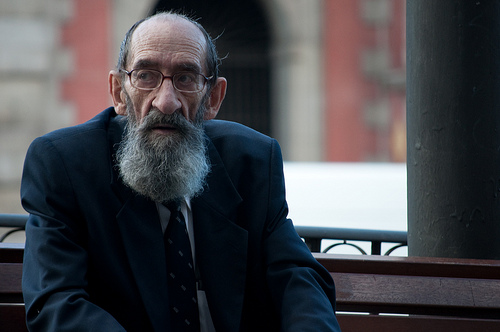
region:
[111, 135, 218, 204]
Long beard on an old man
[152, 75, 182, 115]
Large nose on an old man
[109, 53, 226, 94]
Eyeglasses being worn by an old man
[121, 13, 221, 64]
Receding hair line of an old man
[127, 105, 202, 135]
Scruffy mustache on an old man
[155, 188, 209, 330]
Necktie worn with a suit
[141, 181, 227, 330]
White dress shirt worn with a suit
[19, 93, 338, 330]
Suit worn by old man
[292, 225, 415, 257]
Top of iron railing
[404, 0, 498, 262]
Concrete support post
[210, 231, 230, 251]
the suit is black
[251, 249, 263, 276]
the suit is black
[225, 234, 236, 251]
the suit is black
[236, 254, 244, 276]
the suit is black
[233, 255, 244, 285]
the suit is black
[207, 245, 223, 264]
the suit is black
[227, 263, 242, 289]
the suit is black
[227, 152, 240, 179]
the suit is black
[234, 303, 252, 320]
the suit is black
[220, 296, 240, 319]
the suit is black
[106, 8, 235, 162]
the head of a man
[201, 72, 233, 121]
the ear of a man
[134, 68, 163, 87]
the eye of a man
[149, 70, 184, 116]
the nose of a man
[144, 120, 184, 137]
the mouth of a man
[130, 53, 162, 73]
the eyebrow of a man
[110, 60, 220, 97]
a pair of glasses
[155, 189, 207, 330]
a black necktie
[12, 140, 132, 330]
the arm of a man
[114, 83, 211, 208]
the beard of a man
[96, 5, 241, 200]
a man with a long beard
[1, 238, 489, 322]
back of a wooden bench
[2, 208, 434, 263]
a long metal fence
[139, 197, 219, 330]
a blue patterned tie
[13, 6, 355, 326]
a man wearing a suit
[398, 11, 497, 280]
a large grey pillar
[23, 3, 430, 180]
a red brick building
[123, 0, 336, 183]
a stone arch entryway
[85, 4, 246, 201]
a balding older man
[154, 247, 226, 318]
blue necktie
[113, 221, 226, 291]
blue necktie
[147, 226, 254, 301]
blue necktie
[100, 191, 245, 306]
blue necktie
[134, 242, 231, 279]
blue necktie